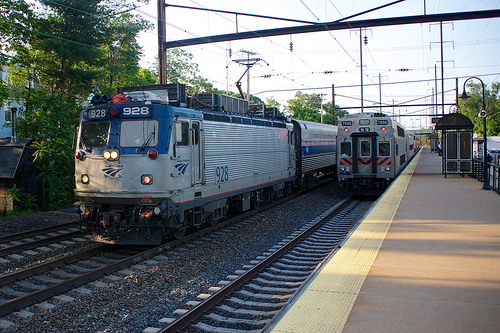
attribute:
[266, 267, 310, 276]
board — wooden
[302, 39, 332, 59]
clouds — white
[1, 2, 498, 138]
sky — blue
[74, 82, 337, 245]
train — long, grey, blue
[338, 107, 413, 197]
train — long, grey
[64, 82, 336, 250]
light rail — silver, blue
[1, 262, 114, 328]
board — wooden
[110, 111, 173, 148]
train — grey, blue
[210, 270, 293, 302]
board — wooden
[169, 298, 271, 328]
board — wooden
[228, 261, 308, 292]
board — wooden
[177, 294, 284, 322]
board — wooden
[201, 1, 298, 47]
cloud — white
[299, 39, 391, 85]
cloud — white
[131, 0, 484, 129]
sky — blue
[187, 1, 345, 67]
cloud — white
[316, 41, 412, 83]
cloud — white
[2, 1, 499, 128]
clouds — white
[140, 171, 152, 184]
headlight — round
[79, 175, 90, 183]
headlight — round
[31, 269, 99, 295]
board — wooden